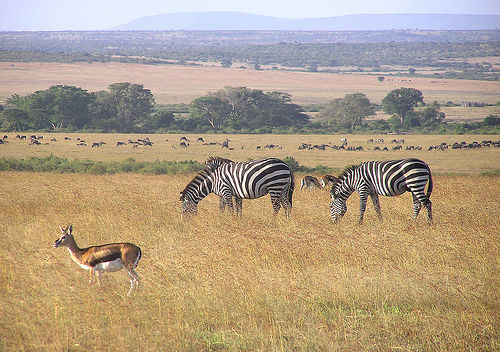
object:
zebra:
[173, 154, 298, 225]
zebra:
[327, 155, 435, 226]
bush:
[0, 77, 500, 347]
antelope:
[49, 222, 146, 299]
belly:
[96, 256, 126, 276]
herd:
[0, 124, 499, 154]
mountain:
[99, 7, 498, 30]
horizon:
[2, 0, 499, 62]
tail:
[422, 165, 434, 207]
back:
[404, 158, 430, 189]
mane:
[181, 160, 225, 198]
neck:
[191, 164, 220, 202]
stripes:
[268, 187, 285, 192]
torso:
[192, 156, 292, 205]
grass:
[1, 169, 500, 352]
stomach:
[231, 184, 273, 200]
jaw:
[188, 200, 200, 217]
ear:
[66, 224, 75, 235]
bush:
[0, 152, 354, 174]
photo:
[0, 0, 500, 352]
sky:
[4, 0, 500, 35]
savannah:
[0, 26, 500, 64]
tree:
[182, 83, 313, 137]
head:
[178, 189, 200, 224]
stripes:
[205, 176, 213, 194]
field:
[0, 131, 499, 349]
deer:
[298, 172, 325, 196]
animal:
[320, 171, 340, 189]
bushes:
[148, 105, 180, 133]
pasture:
[2, 46, 498, 342]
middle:
[4, 82, 499, 176]